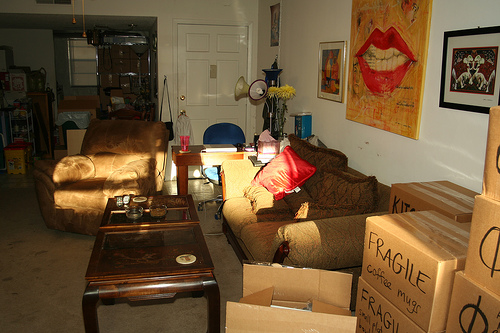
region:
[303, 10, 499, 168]
painting on the wall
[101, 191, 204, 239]
ashtrays on the table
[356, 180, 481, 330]
the boxes are brown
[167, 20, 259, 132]
the door is closed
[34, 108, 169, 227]
the seat is brown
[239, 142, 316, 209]
the pillow is red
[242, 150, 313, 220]
pillow on the couch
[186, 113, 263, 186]
the chair is blue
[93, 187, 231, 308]
the table is brown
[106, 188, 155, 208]
remote controls on table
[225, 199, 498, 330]
Boxes moving in moving out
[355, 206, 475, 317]
Packed box FRAGILE coffee mugs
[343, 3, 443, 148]
Wild red lips wall art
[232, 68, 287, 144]
Pole lamp end couch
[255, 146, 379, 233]
Accent pillows thrown couch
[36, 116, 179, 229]
Suede brown recliner chair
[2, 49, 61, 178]
More items move piled background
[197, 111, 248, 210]
Blue rolling desk chair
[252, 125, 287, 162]
Box tissue ready sneeze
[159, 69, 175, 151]
Purse hangs wall next door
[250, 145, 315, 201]
Red throw pillow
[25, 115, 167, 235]
Brown rocking recliner chair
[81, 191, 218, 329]
Wooden rectangular coffee table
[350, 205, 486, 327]
Box of fragile coffee mugs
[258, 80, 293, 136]
Vase of large yellow flowers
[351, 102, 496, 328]
Stacks of unpacked moving boxes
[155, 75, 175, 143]
Purse hanging from a hook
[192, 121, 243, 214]
Blue rolling desk chair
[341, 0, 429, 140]
Large picture of lips and teeth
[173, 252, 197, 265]
Drink coaster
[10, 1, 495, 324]
a semi-cluttered room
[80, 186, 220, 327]
a brown coffee table with various items on it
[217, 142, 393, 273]
a couch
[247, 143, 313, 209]
a large red cushion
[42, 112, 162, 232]
a large cushioned chair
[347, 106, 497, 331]
boxes piled near wall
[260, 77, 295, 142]
tall yellow flowers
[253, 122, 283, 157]
a facial tissue dispenser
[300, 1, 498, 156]
artwork on wall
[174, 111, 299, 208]
rolling chair behind desk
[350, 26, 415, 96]
Giant red lips with teeth on the wall.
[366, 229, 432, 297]
The word FRAGILE written on the side of a box.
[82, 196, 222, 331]
A long brown wood and glass coffee table.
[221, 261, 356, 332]
An open box on the floor near a coffee table.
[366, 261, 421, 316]
Coffee mugs written on a box under the word FRAGILE.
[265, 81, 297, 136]
Two tall yellow flowers.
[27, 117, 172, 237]
A large brown chair in a living room.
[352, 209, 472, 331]
Two brown boxes stacked up that say FRAGILE on them.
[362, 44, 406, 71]
White teeth on a painting on the wall.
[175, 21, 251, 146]
White door past a blue chair.